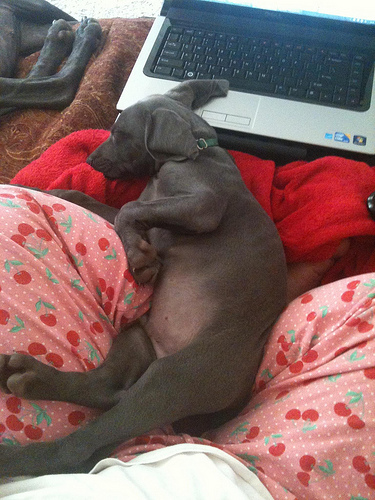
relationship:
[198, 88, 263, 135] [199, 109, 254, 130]
touchpad has mouse buttons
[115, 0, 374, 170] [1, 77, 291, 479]
laptop behind dog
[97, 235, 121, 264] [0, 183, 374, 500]
cherry on woman's pants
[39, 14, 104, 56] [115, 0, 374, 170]
dog's feet by laptop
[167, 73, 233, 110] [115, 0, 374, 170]
ear resting on laptop